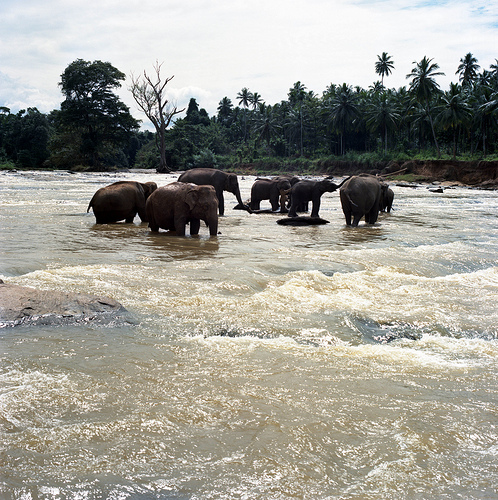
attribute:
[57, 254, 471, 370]
water — brownish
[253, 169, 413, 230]
animal — large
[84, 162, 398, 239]
elephants — small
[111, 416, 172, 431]
ripples — small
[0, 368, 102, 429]
ripples — small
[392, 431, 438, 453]
ripples — small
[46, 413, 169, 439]
ripples — small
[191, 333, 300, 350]
ripples — small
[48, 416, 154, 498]
ripple — small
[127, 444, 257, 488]
ripple — small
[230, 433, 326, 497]
ripple — small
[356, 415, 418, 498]
ripple — small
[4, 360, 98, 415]
ripple — small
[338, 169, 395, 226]
animal — large